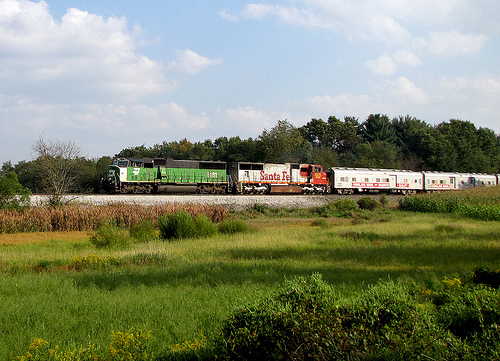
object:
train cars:
[326, 163, 424, 196]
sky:
[0, 1, 500, 167]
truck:
[106, 157, 232, 196]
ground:
[0, 205, 500, 360]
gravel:
[13, 193, 406, 208]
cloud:
[167, 47, 212, 77]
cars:
[326, 165, 425, 193]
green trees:
[0, 158, 34, 211]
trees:
[259, 118, 314, 165]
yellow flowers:
[164, 336, 210, 355]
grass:
[2, 207, 500, 360]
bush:
[192, 266, 500, 360]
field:
[0, 205, 500, 360]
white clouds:
[422, 26, 491, 59]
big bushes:
[0, 199, 227, 234]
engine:
[99, 156, 233, 194]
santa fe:
[257, 169, 290, 181]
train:
[100, 154, 500, 196]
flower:
[105, 326, 120, 340]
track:
[6, 191, 410, 199]